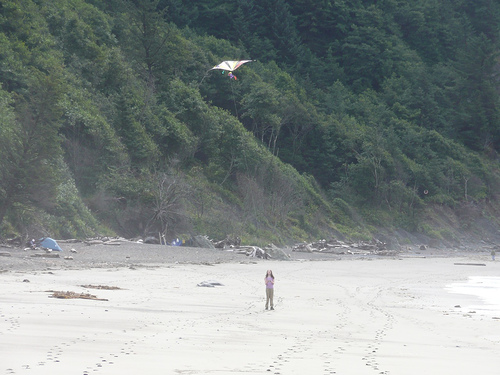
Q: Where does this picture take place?
A: On a beach.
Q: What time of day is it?
A: Afternoon.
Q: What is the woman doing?
A: Flying a kite.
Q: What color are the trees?
A: Green.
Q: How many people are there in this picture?
A: One.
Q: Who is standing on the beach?
A: A woman.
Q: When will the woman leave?
A: When she has finished flying the kite.